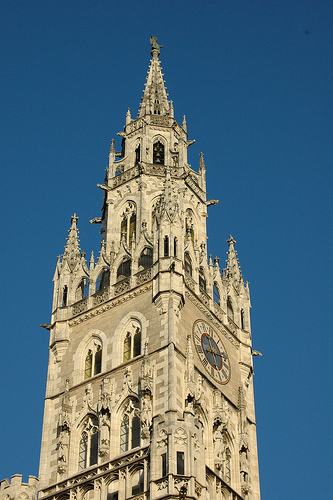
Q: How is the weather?
A: It is clear.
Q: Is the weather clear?
A: Yes, it is clear.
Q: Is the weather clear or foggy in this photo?
A: It is clear.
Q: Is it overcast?
A: No, it is clear.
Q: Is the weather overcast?
A: No, it is clear.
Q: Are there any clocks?
A: Yes, there is a clock.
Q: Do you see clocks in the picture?
A: Yes, there is a clock.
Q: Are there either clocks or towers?
A: Yes, there is a clock.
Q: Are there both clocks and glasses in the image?
A: No, there is a clock but no glasses.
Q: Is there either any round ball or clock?
A: Yes, there is a round clock.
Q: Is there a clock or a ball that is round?
A: Yes, the clock is round.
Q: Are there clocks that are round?
A: Yes, there is a round clock.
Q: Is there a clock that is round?
A: Yes, there is a round clock.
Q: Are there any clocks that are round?
A: Yes, there is a clock that is round.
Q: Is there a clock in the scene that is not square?
A: Yes, there is a round clock.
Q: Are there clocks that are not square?
A: Yes, there is a round clock.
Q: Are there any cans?
A: No, there are no cans.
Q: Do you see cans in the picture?
A: No, there are no cans.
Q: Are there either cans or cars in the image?
A: No, there are no cans or cars.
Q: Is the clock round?
A: Yes, the clock is round.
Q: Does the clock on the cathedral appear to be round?
A: Yes, the clock is round.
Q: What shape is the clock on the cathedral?
A: The clock is round.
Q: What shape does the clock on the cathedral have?
A: The clock has round shape.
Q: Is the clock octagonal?
A: No, the clock is round.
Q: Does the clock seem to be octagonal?
A: No, the clock is round.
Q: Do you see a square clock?
A: No, there is a clock but it is round.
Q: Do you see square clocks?
A: No, there is a clock but it is round.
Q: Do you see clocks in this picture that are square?
A: No, there is a clock but it is round.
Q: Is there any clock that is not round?
A: No, there is a clock but it is round.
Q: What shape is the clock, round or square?
A: The clock is round.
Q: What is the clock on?
A: The clock is on the cathedral.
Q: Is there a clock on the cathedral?
A: Yes, there is a clock on the cathedral.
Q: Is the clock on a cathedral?
A: Yes, the clock is on a cathedral.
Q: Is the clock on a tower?
A: No, the clock is on a cathedral.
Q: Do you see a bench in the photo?
A: No, there are no benches.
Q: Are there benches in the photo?
A: No, there are no benches.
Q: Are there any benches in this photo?
A: No, there are no benches.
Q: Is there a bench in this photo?
A: No, there are no benches.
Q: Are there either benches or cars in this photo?
A: No, there are no benches or cars.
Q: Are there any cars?
A: No, there are no cars.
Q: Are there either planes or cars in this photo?
A: No, there are no cars or planes.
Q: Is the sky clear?
A: Yes, the sky is clear.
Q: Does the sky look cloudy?
A: No, the sky is clear.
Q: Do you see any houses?
A: No, there are no houses.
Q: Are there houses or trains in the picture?
A: No, there are no houses or trains.